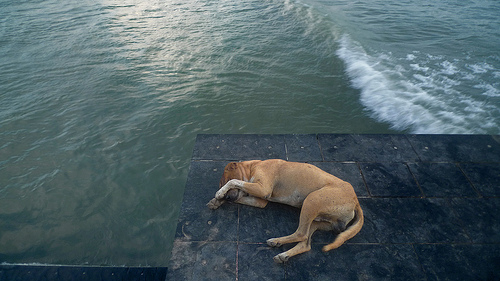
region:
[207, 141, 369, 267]
the dog beside the water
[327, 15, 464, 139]
wave in the water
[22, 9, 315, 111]
the water is calm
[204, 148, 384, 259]
the dog is laying down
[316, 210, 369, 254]
the tail of the dog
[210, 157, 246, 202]
the head of the dog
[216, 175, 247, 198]
the paw over the head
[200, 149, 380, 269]
the dog is beige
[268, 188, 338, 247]
the leg of the dog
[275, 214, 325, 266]
the leg of the dog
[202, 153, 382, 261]
dog lying down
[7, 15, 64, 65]
white and green ocean waves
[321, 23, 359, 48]
white and green ocean waves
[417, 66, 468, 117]
white and green ocean waves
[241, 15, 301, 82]
white and green ocean waves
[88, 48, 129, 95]
white and green ocean waves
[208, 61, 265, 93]
white and green ocean waves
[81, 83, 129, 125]
white and green ocean waves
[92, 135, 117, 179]
white and green ocean waves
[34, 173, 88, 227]
white and green ocean waves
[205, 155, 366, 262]
the dog lying down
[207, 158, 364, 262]
the dog lying down near the water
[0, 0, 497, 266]
the body of water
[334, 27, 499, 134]
the white water in the body of water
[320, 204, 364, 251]
the tail on the dog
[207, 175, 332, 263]
the four legs on the dog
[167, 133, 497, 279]
the platform the dog is lying on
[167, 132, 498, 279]
the platform under the dog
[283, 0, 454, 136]
the small wave in the water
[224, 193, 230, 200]
the nose on the dog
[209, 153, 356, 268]
THAT IS A DOG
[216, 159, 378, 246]
THAT IS A BROWN DOG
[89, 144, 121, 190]
THE WATER IS CALM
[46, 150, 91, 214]
THE WATER IS CALM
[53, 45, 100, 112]
THE WATER IS CALM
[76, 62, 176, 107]
THE WATER IS CALM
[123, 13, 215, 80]
THE WATER IS CALM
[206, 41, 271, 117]
THE WATER IS CALM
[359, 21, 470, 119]
THAT IS A WAVE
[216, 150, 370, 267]
THE DOG IS SLEEPING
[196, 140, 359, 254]
Dog on the shore.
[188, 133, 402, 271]
Blonde dog on the ground.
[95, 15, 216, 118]
Water in the ocean.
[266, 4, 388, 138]
Waves in the ocean.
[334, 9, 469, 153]
White caps on the waves.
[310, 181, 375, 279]
Tail on the dog.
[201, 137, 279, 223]
Dog with its feet on its face.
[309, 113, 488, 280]
black stone in the water.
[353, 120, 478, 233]
Grout between the cracks.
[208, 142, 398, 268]
Dog that is sleeping.